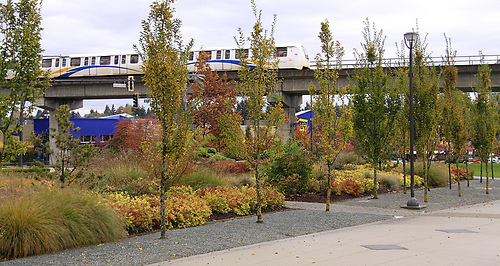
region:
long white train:
[11, 41, 315, 79]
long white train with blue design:
[35, 43, 316, 84]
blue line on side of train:
[55, 58, 133, 89]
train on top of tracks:
[40, 35, 315, 93]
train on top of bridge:
[0, 31, 340, 111]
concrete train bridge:
[8, 65, 446, 196]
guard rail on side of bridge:
[307, 52, 471, 72]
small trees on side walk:
[95, 0, 339, 230]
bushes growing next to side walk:
[4, 182, 134, 247]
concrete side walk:
[325, 198, 490, 265]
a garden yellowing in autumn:
[113, 163, 472, 233]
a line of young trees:
[131, 0, 497, 239]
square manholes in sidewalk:
[359, 221, 477, 253]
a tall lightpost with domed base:
[400, 24, 425, 213]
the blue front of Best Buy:
[36, 108, 336, 145]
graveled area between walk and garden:
[30, 169, 497, 264]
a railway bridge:
[2, 57, 499, 97]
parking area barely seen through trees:
[344, 135, 497, 161]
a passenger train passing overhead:
[36, 40, 308, 77]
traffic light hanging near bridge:
[129, 90, 145, 113]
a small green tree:
[130, 0, 198, 239]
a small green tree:
[217, 5, 283, 223]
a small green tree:
[303, 16, 343, 210]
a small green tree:
[346, 16, 401, 200]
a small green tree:
[397, 26, 437, 196]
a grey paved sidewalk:
[6, 175, 497, 262]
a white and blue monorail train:
[0, 43, 310, 79]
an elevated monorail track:
[0, 57, 497, 96]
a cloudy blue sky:
[0, 3, 497, 65]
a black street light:
[400, 28, 420, 194]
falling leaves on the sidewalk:
[66, 239, 177, 257]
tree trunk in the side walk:
[246, 212, 281, 227]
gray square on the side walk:
[354, 237, 414, 256]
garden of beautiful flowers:
[87, 164, 297, 238]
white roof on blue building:
[277, 101, 327, 121]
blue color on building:
[68, 113, 135, 140]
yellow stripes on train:
[28, 57, 81, 77]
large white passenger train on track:
[88, 36, 330, 81]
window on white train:
[224, 35, 256, 58]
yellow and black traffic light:
[121, 83, 149, 115]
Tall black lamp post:
[399, 29, 424, 210]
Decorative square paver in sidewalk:
[354, 235, 410, 255]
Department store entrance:
[293, 103, 315, 154]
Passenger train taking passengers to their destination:
[30, 40, 325, 70]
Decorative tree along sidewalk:
[125, 0, 199, 235]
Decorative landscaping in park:
[42, 181, 274, 228]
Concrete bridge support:
[261, 82, 306, 164]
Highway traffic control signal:
[116, 74, 140, 95]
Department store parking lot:
[390, 140, 498, 167]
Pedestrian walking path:
[275, 190, 499, 264]